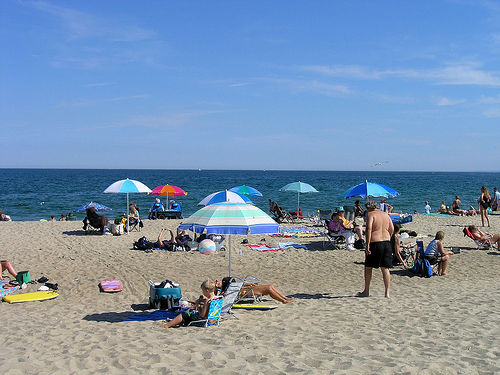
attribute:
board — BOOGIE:
[0, 285, 64, 305]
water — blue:
[4, 166, 497, 223]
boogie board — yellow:
[4, 283, 57, 304]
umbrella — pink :
[118, 177, 313, 264]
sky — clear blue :
[22, 16, 495, 146]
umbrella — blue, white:
[99, 176, 151, 208]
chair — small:
[176, 292, 232, 338]